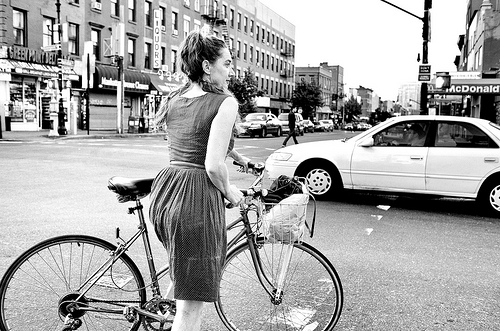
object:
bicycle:
[0, 161, 348, 331]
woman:
[146, 29, 250, 330]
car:
[258, 113, 500, 220]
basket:
[239, 177, 311, 247]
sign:
[152, 8, 161, 70]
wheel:
[0, 233, 148, 331]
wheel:
[215, 235, 343, 331]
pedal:
[123, 306, 139, 325]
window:
[12, 7, 28, 47]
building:
[1, 1, 297, 134]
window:
[125, 37, 137, 69]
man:
[280, 105, 302, 147]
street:
[0, 131, 499, 306]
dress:
[146, 91, 233, 302]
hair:
[180, 29, 226, 93]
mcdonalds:
[446, 84, 500, 92]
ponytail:
[180, 29, 204, 87]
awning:
[418, 77, 500, 100]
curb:
[74, 134, 170, 141]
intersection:
[0, 147, 294, 307]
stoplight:
[433, 73, 453, 93]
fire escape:
[200, 1, 231, 33]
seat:
[107, 174, 154, 203]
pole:
[54, 0, 67, 138]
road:
[0, 136, 165, 166]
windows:
[126, 36, 138, 68]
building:
[456, 1, 499, 120]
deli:
[0, 42, 79, 144]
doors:
[350, 122, 427, 191]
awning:
[96, 63, 152, 98]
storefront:
[86, 88, 146, 133]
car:
[235, 111, 285, 139]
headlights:
[248, 124, 261, 129]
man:
[403, 123, 425, 147]